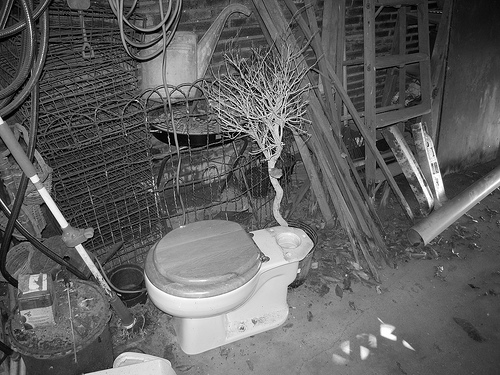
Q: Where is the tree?
A: In the back of the toilet.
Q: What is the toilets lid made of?
A: Wood.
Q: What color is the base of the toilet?
A: White.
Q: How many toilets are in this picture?
A: 1.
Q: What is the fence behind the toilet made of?
A: Metal.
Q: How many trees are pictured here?
A: 1.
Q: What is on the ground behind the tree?
A: Leaves.